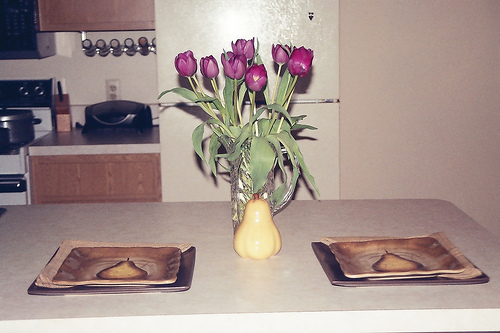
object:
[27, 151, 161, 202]
cabinet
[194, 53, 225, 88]
flowers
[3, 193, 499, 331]
table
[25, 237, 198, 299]
plate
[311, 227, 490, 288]
plate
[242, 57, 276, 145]
flower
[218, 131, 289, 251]
vase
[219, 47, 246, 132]
flower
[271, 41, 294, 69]
flower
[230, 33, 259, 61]
flower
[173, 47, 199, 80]
flower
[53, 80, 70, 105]
knife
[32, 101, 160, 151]
counter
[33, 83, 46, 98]
knob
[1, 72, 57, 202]
stove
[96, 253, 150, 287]
pear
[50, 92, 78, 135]
wooden block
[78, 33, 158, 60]
rack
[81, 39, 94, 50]
spices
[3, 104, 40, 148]
pot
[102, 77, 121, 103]
electric outlet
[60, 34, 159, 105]
wall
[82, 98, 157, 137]
player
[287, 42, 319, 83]
tulip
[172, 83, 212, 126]
stem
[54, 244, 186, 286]
napkin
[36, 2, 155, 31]
cabinet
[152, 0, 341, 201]
refrigerator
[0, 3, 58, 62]
microwave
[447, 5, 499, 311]
right side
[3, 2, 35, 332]
left side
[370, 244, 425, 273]
pear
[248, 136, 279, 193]
leaves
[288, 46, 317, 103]
roses